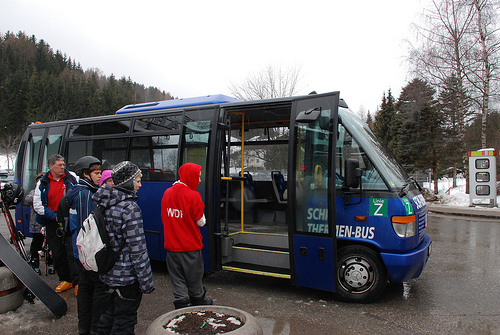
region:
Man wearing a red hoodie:
[158, 156, 212, 303]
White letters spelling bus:
[350, 223, 378, 240]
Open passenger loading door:
[207, 87, 324, 290]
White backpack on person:
[72, 198, 117, 283]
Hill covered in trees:
[0, 31, 91, 148]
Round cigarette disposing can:
[148, 300, 269, 333]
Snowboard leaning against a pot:
[0, 226, 72, 322]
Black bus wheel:
[320, 244, 395, 309]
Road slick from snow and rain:
[412, 210, 494, 332]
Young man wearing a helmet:
[69, 153, 108, 193]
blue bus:
[213, 85, 416, 290]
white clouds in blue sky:
[31, 7, 91, 37]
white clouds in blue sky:
[52, 1, 84, 45]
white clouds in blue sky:
[82, 0, 110, 55]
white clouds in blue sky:
[111, 10, 146, 60]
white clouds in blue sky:
[168, 7, 219, 87]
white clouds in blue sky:
[213, 16, 273, 74]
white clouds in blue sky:
[300, 9, 344, 67]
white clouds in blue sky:
[345, 7, 380, 71]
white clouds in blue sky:
[331, 18, 382, 85]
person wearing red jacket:
[156, 164, 218, 294]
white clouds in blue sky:
[13, 8, 59, 31]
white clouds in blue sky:
[86, 15, 103, 50]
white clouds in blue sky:
[116, 8, 158, 91]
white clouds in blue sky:
[161, 30, 202, 83]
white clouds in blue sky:
[209, 17, 246, 72]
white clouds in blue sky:
[247, 17, 288, 70]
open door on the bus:
[211, 98, 293, 286]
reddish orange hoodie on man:
[162, 163, 205, 251]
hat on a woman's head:
[112, 161, 142, 194]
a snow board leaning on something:
[0, 229, 66, 319]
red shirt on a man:
[47, 172, 67, 209]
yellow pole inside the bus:
[237, 112, 249, 232]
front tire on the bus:
[332, 246, 382, 302]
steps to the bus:
[225, 230, 290, 277]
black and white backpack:
[75, 203, 114, 274]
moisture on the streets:
[426, 211, 498, 333]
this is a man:
[147, 148, 230, 325]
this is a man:
[78, 153, 172, 332]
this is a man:
[60, 155, 126, 330]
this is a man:
[26, 152, 105, 325]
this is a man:
[18, 178, 69, 278]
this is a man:
[82, 172, 132, 195]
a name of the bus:
[331, 215, 386, 250]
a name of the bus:
[289, 200, 341, 223]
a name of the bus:
[300, 206, 337, 243]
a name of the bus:
[329, 205, 353, 239]